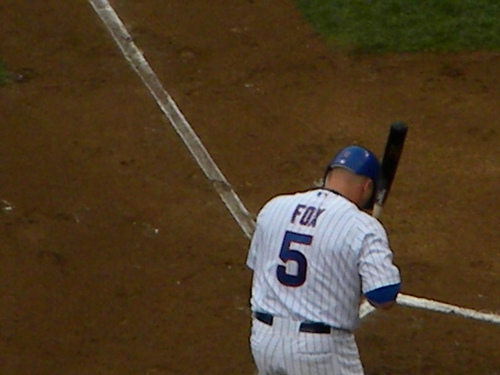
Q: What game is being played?
A: Baseball.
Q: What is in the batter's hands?
A: Bat.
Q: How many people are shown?
A: One.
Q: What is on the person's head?
A: Helmet.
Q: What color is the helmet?
A: Blue.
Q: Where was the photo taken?
A: Ballpark.